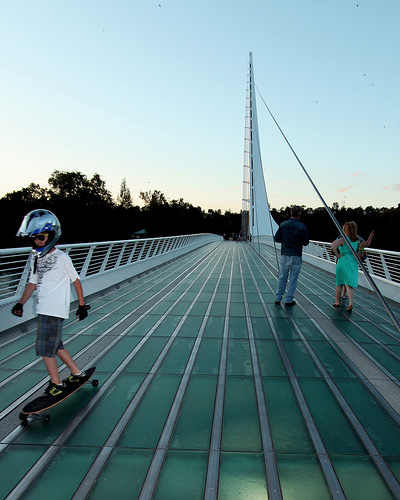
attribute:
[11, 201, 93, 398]
boy — skateboarding, young, skateboard, riding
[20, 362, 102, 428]
skateboard — black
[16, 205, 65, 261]
helmet — shiny, silver, metallic, colored, blue, large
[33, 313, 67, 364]
shorts — plaid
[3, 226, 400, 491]
bridge — steel, colored, green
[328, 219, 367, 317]
woman — walking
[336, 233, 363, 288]
dress — green, blue, knee length, greenish, colored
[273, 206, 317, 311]
man — walking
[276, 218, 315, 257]
shirt — blue, black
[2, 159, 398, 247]
trees — growing, dark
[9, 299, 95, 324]
gloves — athletic, black, fingerless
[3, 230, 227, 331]
railing — side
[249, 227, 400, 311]
railing — white, side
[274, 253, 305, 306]
jeans — blue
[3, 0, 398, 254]
sky — clear, blue, above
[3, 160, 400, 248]
landscape — trees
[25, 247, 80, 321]
t-shirt — white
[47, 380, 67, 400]
sneaker — black, yellow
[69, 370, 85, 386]
sneaker — black, yellow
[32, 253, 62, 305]
design — black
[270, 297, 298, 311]
shoes — black, yellow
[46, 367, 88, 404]
shoes — black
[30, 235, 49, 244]
suglasses — dark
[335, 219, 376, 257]
woman — pointing